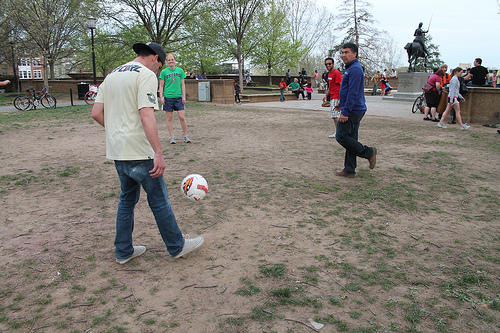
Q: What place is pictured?
A: It is a park.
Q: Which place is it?
A: It is a park.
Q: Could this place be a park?
A: Yes, it is a park.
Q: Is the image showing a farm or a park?
A: It is showing a park.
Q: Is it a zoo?
A: No, it is a park.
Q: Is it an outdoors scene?
A: Yes, it is outdoors.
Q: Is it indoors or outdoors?
A: It is outdoors.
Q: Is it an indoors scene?
A: No, it is outdoors.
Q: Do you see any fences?
A: No, there are no fences.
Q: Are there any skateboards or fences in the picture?
A: No, there are no fences or skateboards.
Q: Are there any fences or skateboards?
A: No, there are no fences or skateboards.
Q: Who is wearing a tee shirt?
A: The soccer player is wearing a tee shirt.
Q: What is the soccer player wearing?
A: The soccer player is wearing a tee shirt.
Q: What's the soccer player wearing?
A: The soccer player is wearing a tee shirt.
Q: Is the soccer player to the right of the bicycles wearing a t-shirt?
A: Yes, the soccer player is wearing a t-shirt.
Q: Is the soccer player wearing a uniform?
A: No, the soccer player is wearing a t-shirt.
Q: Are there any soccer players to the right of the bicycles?
A: Yes, there is a soccer player to the right of the bicycles.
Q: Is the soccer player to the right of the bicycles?
A: Yes, the soccer player is to the right of the bicycles.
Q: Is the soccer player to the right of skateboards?
A: No, the soccer player is to the right of the bicycles.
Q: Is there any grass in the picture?
A: Yes, there is grass.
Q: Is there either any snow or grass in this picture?
A: Yes, there is grass.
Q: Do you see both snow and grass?
A: No, there is grass but no snow.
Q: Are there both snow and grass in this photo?
A: No, there is grass but no snow.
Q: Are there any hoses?
A: No, there are no hoses.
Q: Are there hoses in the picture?
A: No, there are no hoses.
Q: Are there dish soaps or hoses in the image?
A: No, there are no hoses or dish soaps.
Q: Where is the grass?
A: The grass is on the ground.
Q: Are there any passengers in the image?
A: No, there are no passengers.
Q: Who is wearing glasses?
A: The man is wearing glasses.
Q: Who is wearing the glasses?
A: The man is wearing glasses.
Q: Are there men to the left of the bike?
A: Yes, there is a man to the left of the bike.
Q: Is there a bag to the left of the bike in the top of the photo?
A: No, there is a man to the left of the bike.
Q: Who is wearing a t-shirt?
A: The man is wearing a t-shirt.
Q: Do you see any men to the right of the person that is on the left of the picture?
A: Yes, there is a man to the right of the guy.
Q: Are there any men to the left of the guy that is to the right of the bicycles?
A: No, the man is to the right of the guy.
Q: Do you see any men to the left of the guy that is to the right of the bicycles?
A: No, the man is to the right of the guy.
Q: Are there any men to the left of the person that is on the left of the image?
A: No, the man is to the right of the guy.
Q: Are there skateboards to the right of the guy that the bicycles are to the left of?
A: No, there is a man to the right of the guy.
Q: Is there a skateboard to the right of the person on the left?
A: No, there is a man to the right of the guy.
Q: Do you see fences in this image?
A: No, there are no fences.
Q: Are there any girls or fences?
A: No, there are no fences or girls.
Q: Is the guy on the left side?
A: Yes, the guy is on the left of the image.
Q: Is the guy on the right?
A: No, the guy is on the left of the image.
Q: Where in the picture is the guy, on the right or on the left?
A: The guy is on the left of the image.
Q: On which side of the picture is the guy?
A: The guy is on the left of the image.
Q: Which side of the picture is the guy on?
A: The guy is on the left of the image.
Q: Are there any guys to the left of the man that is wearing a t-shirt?
A: Yes, there is a guy to the left of the man.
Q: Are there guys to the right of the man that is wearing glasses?
A: No, the guy is to the left of the man.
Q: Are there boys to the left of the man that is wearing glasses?
A: No, there is a guy to the left of the man.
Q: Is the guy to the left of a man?
A: Yes, the guy is to the left of a man.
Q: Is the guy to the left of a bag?
A: No, the guy is to the left of a man.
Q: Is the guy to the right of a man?
A: No, the guy is to the left of a man.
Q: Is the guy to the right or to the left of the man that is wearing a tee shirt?
A: The guy is to the left of the man.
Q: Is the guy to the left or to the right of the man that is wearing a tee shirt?
A: The guy is to the left of the man.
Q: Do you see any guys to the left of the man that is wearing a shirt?
A: Yes, there is a guy to the left of the man.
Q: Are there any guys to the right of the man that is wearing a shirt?
A: No, the guy is to the left of the man.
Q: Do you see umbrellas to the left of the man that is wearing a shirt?
A: No, there is a guy to the left of the man.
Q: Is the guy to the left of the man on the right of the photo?
A: Yes, the guy is to the left of the man.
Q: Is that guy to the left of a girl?
A: No, the guy is to the left of the man.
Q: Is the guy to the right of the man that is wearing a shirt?
A: No, the guy is to the left of the man.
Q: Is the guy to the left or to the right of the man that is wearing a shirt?
A: The guy is to the left of the man.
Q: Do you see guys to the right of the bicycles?
A: Yes, there is a guy to the right of the bicycles.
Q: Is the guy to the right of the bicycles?
A: Yes, the guy is to the right of the bicycles.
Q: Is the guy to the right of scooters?
A: No, the guy is to the right of the bicycles.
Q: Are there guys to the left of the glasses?
A: Yes, there is a guy to the left of the glasses.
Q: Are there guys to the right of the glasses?
A: No, the guy is to the left of the glasses.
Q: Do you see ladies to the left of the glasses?
A: No, there is a guy to the left of the glasses.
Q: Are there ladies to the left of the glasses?
A: No, there is a guy to the left of the glasses.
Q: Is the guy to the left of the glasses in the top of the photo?
A: Yes, the guy is to the left of the glasses.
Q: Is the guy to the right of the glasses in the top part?
A: No, the guy is to the left of the glasses.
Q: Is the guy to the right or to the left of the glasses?
A: The guy is to the left of the glasses.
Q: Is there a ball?
A: Yes, there is a ball.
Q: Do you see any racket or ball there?
A: Yes, there is a ball.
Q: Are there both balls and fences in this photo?
A: No, there is a ball but no fences.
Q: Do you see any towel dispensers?
A: No, there are no towel dispensers.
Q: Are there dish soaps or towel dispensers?
A: No, there are no towel dispensers or dish soaps.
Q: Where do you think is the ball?
A: The ball is in the park.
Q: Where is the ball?
A: The ball is in the park.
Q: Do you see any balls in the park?
A: Yes, there is a ball in the park.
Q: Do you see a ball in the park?
A: Yes, there is a ball in the park.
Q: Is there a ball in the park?
A: Yes, there is a ball in the park.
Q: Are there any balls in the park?
A: Yes, there is a ball in the park.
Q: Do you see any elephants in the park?
A: No, there is a ball in the park.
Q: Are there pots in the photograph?
A: No, there are no pots.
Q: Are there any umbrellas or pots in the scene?
A: No, there are no pots or umbrellas.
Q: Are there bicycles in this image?
A: Yes, there are bicycles.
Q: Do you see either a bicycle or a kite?
A: Yes, there are bicycles.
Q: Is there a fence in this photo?
A: No, there are no fences.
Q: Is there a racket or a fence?
A: No, there are no fences or rackets.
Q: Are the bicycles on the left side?
A: Yes, the bicycles are on the left of the image.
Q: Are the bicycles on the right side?
A: No, the bicycles are on the left of the image.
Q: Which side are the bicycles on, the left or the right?
A: The bicycles are on the left of the image.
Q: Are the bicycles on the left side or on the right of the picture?
A: The bicycles are on the left of the image.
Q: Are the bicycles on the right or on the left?
A: The bicycles are on the left of the image.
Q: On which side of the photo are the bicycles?
A: The bicycles are on the left of the image.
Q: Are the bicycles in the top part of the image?
A: Yes, the bicycles are in the top of the image.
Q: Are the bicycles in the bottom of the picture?
A: No, the bicycles are in the top of the image.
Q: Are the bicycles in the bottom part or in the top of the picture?
A: The bicycles are in the top of the image.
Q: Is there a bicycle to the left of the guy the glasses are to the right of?
A: Yes, there are bicycles to the left of the guy.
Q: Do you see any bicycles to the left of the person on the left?
A: Yes, there are bicycles to the left of the guy.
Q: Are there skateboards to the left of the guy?
A: No, there are bicycles to the left of the guy.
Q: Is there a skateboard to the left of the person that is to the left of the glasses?
A: No, there are bicycles to the left of the guy.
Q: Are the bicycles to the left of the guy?
A: Yes, the bicycles are to the left of the guy.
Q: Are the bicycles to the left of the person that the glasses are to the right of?
A: Yes, the bicycles are to the left of the guy.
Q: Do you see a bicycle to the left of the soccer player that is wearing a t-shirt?
A: Yes, there are bicycles to the left of the soccer player.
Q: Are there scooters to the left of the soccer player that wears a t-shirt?
A: No, there are bicycles to the left of the soccer player.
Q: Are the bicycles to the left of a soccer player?
A: Yes, the bicycles are to the left of a soccer player.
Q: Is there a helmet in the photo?
A: No, there are no helmets.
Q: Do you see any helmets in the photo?
A: No, there are no helmets.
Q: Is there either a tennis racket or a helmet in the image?
A: No, there are no helmets or rackets.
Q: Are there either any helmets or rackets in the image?
A: No, there are no helmets or rackets.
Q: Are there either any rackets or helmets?
A: No, there are no helmets or rackets.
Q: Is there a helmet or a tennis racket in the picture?
A: No, there are no helmets or rackets.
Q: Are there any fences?
A: No, there are no fences.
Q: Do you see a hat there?
A: Yes, there is a hat.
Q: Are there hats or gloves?
A: Yes, there is a hat.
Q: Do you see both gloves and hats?
A: No, there is a hat but no gloves.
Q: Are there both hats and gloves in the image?
A: No, there is a hat but no gloves.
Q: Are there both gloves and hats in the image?
A: No, there is a hat but no gloves.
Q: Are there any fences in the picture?
A: No, there are no fences.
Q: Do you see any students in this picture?
A: No, there are no students.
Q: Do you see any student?
A: No, there are no students.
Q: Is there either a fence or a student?
A: No, there are no students or fences.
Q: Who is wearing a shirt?
A: The man is wearing a shirt.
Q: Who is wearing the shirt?
A: The man is wearing a shirt.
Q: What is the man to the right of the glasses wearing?
A: The man is wearing a shirt.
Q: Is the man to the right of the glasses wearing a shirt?
A: Yes, the man is wearing a shirt.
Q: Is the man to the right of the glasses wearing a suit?
A: No, the man is wearing a shirt.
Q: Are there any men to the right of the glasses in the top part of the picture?
A: Yes, there is a man to the right of the glasses.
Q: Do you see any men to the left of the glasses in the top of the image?
A: No, the man is to the right of the glasses.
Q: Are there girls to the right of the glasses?
A: No, there is a man to the right of the glasses.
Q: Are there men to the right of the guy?
A: Yes, there is a man to the right of the guy.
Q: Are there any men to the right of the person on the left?
A: Yes, there is a man to the right of the guy.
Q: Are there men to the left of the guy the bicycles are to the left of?
A: No, the man is to the right of the guy.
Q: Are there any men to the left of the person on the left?
A: No, the man is to the right of the guy.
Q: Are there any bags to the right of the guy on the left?
A: No, there is a man to the right of the guy.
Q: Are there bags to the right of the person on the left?
A: No, there is a man to the right of the guy.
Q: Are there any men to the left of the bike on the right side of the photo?
A: Yes, there is a man to the left of the bike.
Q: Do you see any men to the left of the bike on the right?
A: Yes, there is a man to the left of the bike.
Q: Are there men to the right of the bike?
A: No, the man is to the left of the bike.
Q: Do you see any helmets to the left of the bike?
A: No, there is a man to the left of the bike.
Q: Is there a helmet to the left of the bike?
A: No, there is a man to the left of the bike.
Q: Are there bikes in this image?
A: Yes, there is a bike.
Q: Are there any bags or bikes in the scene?
A: Yes, there is a bike.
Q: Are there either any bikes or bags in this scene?
A: Yes, there is a bike.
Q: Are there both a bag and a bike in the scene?
A: No, there is a bike but no bags.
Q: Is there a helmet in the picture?
A: No, there are no helmets.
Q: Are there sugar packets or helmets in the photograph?
A: No, there are no helmets or sugar packets.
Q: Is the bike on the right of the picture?
A: Yes, the bike is on the right of the image.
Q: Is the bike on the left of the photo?
A: No, the bike is on the right of the image.